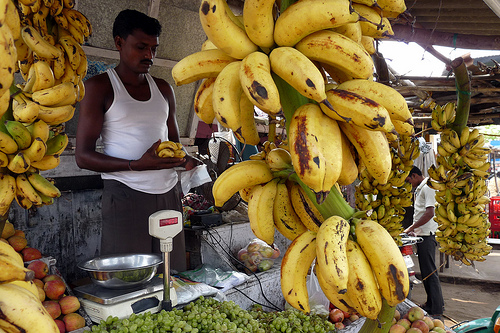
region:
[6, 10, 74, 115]
yellow gren and black bananas in market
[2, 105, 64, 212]
yellow gren and black bananas in market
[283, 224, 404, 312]
yellow gren and black bananas in market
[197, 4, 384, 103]
yellow gren and black bananas in market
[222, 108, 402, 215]
yellow gren and black bananas in market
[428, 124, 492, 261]
yellow gren and black bananas in market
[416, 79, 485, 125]
yellow gren and black bananas in market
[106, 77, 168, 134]
man wearing white tank top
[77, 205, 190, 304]
white and silver scale in market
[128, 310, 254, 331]
green grapes on table in market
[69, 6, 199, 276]
a man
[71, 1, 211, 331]
a man standing behind a scale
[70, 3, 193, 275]
the man is holding bananas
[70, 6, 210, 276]
the man holding the bananas is wearing a white shirt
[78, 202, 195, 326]
a metal bowl sits on a scale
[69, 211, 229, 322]
a scale is in front of the man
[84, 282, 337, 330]
green grapes are in front of the scale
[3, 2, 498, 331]
yellow bananas are hanging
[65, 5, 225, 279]
the man is holding four bananas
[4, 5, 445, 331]
a fruit stand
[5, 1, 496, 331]
the bananas are yellow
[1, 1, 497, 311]
bananas have brown spots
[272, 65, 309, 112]
the banana is green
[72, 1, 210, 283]
man holding bananas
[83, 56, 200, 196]
man's shirt is white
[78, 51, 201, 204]
man is wearing tank top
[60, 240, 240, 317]
silver scale on counter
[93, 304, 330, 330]
grapes next to bananas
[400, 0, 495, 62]
ceiling made of wood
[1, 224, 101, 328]
peaches are behind bananas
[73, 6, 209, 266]
Street Vendor Selling Bannanas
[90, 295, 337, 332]
Bunches of Green Grapes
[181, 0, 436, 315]
Large hanging Seeded Bannanas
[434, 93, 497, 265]
Bunches of Seedless Bannanas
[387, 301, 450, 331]
Pile of Delicious Apples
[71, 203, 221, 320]
Fruit Vendors Scale with Red Display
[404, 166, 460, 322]
Man Shopping on the Street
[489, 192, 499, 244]
Stacked Red Milk Crates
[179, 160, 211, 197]
White Sheet of Paper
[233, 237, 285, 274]
Bag of Delicious Fruit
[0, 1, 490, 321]
Banana is hanging upside down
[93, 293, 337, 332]
Grapes are light green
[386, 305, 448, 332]
Apples on bottom right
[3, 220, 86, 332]
Apples left of school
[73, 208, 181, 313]
Scale with digital readout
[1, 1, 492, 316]
Bananas are yellow and brown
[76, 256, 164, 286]
Large metal bowl on scale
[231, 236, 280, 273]
Already bagged fruit on counter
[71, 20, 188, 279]
Man standing behind counter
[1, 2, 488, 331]
Fruit stand with many fruits